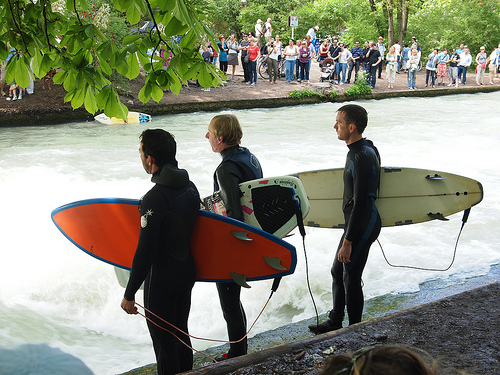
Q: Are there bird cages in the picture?
A: No, there are no bird cages.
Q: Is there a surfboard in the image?
A: Yes, there is a surfboard.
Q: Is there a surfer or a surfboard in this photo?
A: Yes, there is a surfboard.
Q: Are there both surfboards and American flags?
A: No, there is a surfboard but no American flags.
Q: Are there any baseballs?
A: No, there are no baseballs.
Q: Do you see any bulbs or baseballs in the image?
A: No, there are no baseballs or bulbs.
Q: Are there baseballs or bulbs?
A: No, there are no baseballs or bulbs.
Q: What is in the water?
A: The surfboard is in the water.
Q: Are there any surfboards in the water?
A: Yes, there is a surfboard in the water.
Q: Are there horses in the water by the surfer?
A: No, there is a surfboard in the water.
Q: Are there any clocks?
A: No, there are no clocks.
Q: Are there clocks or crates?
A: No, there are no clocks or crates.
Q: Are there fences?
A: No, there are no fences.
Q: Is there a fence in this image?
A: No, there are no fences.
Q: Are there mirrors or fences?
A: No, there are no fences or mirrors.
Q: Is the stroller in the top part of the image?
A: Yes, the stroller is in the top of the image.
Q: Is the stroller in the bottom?
A: No, the stroller is in the top of the image.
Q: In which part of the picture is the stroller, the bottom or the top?
A: The stroller is in the top of the image.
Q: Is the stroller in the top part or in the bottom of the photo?
A: The stroller is in the top of the image.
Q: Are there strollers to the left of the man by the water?
A: Yes, there is a stroller to the left of the man.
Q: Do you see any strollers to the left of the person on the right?
A: Yes, there is a stroller to the left of the man.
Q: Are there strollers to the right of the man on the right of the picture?
A: No, the stroller is to the left of the man.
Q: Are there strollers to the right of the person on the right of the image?
A: No, the stroller is to the left of the man.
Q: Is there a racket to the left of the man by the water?
A: No, there is a stroller to the left of the man.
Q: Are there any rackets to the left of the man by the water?
A: No, there is a stroller to the left of the man.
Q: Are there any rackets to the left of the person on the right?
A: No, there is a stroller to the left of the man.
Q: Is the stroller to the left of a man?
A: Yes, the stroller is to the left of a man.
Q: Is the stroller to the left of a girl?
A: No, the stroller is to the left of a man.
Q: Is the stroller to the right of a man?
A: No, the stroller is to the left of a man.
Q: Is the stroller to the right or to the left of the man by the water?
A: The stroller is to the left of the man.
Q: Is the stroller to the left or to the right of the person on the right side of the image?
A: The stroller is to the left of the man.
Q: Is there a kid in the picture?
A: No, there are no children.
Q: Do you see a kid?
A: No, there are no children.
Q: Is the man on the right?
A: Yes, the man is on the right of the image.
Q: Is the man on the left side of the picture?
A: No, the man is on the right of the image.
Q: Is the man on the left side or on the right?
A: The man is on the right of the image.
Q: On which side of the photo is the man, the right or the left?
A: The man is on the right of the image.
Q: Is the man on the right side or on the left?
A: The man is on the right of the image.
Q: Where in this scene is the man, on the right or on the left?
A: The man is on the right of the image.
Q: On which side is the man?
A: The man is on the right of the image.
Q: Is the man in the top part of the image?
A: Yes, the man is in the top of the image.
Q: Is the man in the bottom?
A: No, the man is in the top of the image.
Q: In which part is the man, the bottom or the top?
A: The man is in the top of the image.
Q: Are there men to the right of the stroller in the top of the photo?
A: Yes, there is a man to the right of the stroller.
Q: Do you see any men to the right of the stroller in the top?
A: Yes, there is a man to the right of the stroller.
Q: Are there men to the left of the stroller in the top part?
A: No, the man is to the right of the stroller.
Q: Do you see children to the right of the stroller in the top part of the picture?
A: No, there is a man to the right of the stroller.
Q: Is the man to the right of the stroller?
A: Yes, the man is to the right of the stroller.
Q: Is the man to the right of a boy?
A: No, the man is to the right of the stroller.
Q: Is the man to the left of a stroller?
A: No, the man is to the right of a stroller.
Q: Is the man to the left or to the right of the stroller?
A: The man is to the right of the stroller.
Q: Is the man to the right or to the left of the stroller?
A: The man is to the right of the stroller.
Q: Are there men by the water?
A: Yes, there is a man by the water.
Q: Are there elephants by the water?
A: No, there is a man by the water.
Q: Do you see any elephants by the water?
A: No, there is a man by the water.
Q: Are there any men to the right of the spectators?
A: Yes, there is a man to the right of the spectators.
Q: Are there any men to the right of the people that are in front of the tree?
A: Yes, there is a man to the right of the spectators.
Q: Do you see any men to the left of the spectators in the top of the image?
A: No, the man is to the right of the spectators.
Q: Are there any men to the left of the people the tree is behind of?
A: No, the man is to the right of the spectators.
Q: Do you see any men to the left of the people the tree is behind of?
A: No, the man is to the right of the spectators.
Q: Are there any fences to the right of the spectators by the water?
A: No, there is a man to the right of the spectators.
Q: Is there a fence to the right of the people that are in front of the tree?
A: No, there is a man to the right of the spectators.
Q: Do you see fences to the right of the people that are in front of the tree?
A: No, there is a man to the right of the spectators.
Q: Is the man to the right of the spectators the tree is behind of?
A: Yes, the man is to the right of the spectators.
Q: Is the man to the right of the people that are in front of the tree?
A: Yes, the man is to the right of the spectators.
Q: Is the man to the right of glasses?
A: No, the man is to the right of the spectators.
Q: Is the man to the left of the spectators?
A: No, the man is to the right of the spectators.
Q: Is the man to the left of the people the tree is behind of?
A: No, the man is to the right of the spectators.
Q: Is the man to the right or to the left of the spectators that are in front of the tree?
A: The man is to the right of the spectators.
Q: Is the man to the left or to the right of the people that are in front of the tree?
A: The man is to the right of the spectators.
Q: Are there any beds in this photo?
A: No, there are no beds.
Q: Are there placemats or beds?
A: No, there are no beds or placemats.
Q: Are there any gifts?
A: No, there are no gifts.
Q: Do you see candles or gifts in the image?
A: No, there are no gifts or candles.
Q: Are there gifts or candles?
A: No, there are no gifts or candles.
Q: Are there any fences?
A: No, there are no fences.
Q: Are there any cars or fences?
A: No, there are no fences or cars.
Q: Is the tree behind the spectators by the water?
A: Yes, the tree is behind the spectators.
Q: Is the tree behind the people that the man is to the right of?
A: Yes, the tree is behind the spectators.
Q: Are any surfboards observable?
A: Yes, there is a surfboard.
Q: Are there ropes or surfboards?
A: Yes, there is a surfboard.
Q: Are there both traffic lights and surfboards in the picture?
A: No, there is a surfboard but no traffic lights.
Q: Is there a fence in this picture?
A: No, there are no fences.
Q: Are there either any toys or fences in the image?
A: No, there are no fences or toys.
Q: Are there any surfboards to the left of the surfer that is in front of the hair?
A: Yes, there is a surfboard to the left of the surfer.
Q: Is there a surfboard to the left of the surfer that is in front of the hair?
A: Yes, there is a surfboard to the left of the surfer.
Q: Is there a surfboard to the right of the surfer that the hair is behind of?
A: No, the surfboard is to the left of the surfer.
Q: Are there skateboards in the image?
A: No, there are no skateboards.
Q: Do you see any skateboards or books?
A: No, there are no skateboards or books.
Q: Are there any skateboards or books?
A: No, there are no skateboards or books.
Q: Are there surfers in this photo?
A: Yes, there is a surfer.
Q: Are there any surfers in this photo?
A: Yes, there is a surfer.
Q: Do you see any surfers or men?
A: Yes, there is a surfer.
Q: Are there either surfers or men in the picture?
A: Yes, there is a surfer.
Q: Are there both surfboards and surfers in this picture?
A: Yes, there are both a surfer and a surfboard.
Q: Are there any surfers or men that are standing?
A: Yes, the surfer is standing.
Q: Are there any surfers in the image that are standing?
A: Yes, there is a surfer that is standing.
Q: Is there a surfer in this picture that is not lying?
A: Yes, there is a surfer that is standing.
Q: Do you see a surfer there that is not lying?
A: Yes, there is a surfer that is standing .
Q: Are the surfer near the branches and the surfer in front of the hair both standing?
A: Yes, both the surfer and the surfer are standing.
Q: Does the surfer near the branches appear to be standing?
A: Yes, the surfer is standing.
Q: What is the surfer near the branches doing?
A: The surfer is standing.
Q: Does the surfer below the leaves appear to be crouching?
A: No, the surfer is standing.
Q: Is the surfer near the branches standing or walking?
A: The surfer is standing.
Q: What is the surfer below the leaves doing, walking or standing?
A: The surfer is standing.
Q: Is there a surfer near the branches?
A: Yes, there is a surfer near the branches.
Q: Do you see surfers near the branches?
A: Yes, there is a surfer near the branches.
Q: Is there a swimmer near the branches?
A: No, there is a surfer near the branches.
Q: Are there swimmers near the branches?
A: No, there is a surfer near the branches.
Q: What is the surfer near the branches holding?
A: The surfer is holding the surf board.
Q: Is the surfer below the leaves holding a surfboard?
A: Yes, the surfer is holding a surfboard.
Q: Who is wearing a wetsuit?
A: The surfer is wearing a wetsuit.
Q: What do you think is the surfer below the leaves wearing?
A: The surfer is wearing a wetsuit.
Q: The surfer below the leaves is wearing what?
A: The surfer is wearing a wetsuit.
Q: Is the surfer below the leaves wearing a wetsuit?
A: Yes, the surfer is wearing a wetsuit.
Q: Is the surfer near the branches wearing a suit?
A: No, the surfer is wearing a wetsuit.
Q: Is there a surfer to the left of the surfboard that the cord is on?
A: Yes, there is a surfer to the left of the surfboard.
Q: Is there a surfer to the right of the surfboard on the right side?
A: No, the surfer is to the left of the surfboard.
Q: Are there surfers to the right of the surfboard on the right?
A: No, the surfer is to the left of the surfboard.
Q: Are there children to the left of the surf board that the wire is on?
A: No, there is a surfer to the left of the surfboard.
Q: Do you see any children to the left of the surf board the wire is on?
A: No, there is a surfer to the left of the surfboard.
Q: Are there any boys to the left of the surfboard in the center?
A: No, there is a surfer to the left of the surf board.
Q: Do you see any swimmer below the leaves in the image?
A: No, there is a surfer below the leaves.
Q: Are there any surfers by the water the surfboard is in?
A: Yes, there is a surfer by the water.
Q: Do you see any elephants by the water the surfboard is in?
A: No, there is a surfer by the water.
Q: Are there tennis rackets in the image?
A: No, there are no tennis rackets.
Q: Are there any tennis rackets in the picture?
A: No, there are no tennis rackets.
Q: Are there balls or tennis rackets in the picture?
A: No, there are no tennis rackets or balls.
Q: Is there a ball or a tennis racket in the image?
A: No, there are no rackets or balls.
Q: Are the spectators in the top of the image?
A: Yes, the spectators are in the top of the image.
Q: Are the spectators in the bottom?
A: No, the spectators are in the top of the image.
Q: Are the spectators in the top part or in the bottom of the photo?
A: The spectators are in the top of the image.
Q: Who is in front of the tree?
A: The spectators are in front of the tree.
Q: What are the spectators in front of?
A: The spectators are in front of the tree.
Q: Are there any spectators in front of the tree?
A: Yes, there are spectators in front of the tree.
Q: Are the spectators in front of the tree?
A: Yes, the spectators are in front of the tree.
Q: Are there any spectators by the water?
A: Yes, there are spectators by the water.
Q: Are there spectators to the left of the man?
A: Yes, there are spectators to the left of the man.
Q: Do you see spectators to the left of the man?
A: Yes, there are spectators to the left of the man.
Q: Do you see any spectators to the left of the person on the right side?
A: Yes, there are spectators to the left of the man.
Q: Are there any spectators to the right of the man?
A: No, the spectators are to the left of the man.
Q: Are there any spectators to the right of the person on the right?
A: No, the spectators are to the left of the man.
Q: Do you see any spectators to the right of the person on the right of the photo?
A: No, the spectators are to the left of the man.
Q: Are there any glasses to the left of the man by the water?
A: No, there are spectators to the left of the man.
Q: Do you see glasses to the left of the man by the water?
A: No, there are spectators to the left of the man.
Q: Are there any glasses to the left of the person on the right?
A: No, there are spectators to the left of the man.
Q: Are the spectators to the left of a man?
A: Yes, the spectators are to the left of a man.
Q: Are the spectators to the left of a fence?
A: No, the spectators are to the left of a man.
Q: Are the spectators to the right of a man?
A: No, the spectators are to the left of a man.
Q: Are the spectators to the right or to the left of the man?
A: The spectators are to the left of the man.